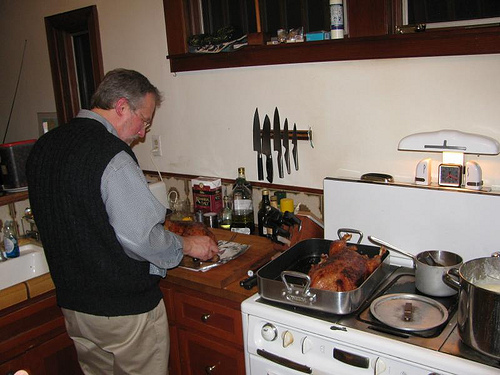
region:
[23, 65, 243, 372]
man preparing food on wooden counter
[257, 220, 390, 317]
roasted chicken in rectangular metal pan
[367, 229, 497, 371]
pots and lids on top of stove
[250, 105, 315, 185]
knives hanging on wall with pointed sides up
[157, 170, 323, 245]
bottles, packages and knives on back counter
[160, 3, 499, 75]
dark windows with packages placed on sills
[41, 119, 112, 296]
A black sweater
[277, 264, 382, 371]
An oven in the kitchen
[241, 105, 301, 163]
Knives in the kitchen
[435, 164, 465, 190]
A clock on the shelf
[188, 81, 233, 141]
A wall in the kitchen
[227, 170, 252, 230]
A bottle in the kitchen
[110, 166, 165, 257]
A gray shirt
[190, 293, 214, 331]
Knob on the drawer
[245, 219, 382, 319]
A tray with chicken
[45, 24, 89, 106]
A door in the kitchen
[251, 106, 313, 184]
knives are arranged one beside the other on the rack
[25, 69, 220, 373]
the person is looking through his eye glasses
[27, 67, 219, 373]
the man is touching the meat with his right hand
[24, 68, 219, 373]
the guy is wearing a black sweater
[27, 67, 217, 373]
the man is wearing brown color pants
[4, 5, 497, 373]
the person is making his dinner in the kitchen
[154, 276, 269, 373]
the cupboard is made of wood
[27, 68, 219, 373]
the man has turned up his sleeves to prevent stains on his shirt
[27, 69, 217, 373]
the guy is wearing gray color shirt inside the black sweater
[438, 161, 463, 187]
the clock with time twenty past seven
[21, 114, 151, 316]
man wearing black sweater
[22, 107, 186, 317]
man wearing blue oxford shirt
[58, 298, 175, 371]
man wearing khaki pants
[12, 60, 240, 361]
older man cooking in kitchen